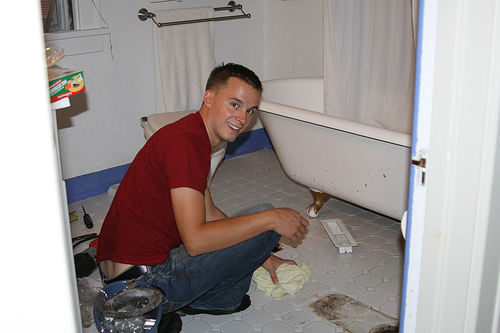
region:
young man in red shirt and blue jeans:
[90, 40, 305, 321]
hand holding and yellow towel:
[252, 249, 311, 303]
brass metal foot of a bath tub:
[301, 175, 336, 221]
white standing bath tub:
[242, 50, 416, 245]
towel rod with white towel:
[131, 2, 266, 120]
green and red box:
[43, 45, 92, 117]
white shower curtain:
[315, 0, 431, 145]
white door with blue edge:
[387, 0, 498, 332]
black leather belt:
[94, 252, 155, 289]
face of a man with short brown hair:
[197, 55, 271, 149]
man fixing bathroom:
[107, 52, 294, 322]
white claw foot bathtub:
[242, 58, 414, 233]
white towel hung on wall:
[142, 0, 257, 110]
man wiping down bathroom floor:
[243, 202, 341, 307]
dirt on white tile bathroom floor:
[307, 280, 370, 325]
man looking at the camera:
[105, 57, 278, 307]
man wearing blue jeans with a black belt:
[105, 196, 330, 324]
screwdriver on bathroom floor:
[76, 191, 101, 246]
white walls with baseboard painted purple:
[76, 125, 132, 202]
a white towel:
[130, 5, 252, 122]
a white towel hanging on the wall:
[130, 10, 257, 139]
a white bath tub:
[257, 53, 438, 240]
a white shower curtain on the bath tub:
[256, 0, 456, 217]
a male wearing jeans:
[116, 50, 284, 313]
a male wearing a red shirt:
[132, 57, 326, 289]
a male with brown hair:
[138, 40, 352, 279]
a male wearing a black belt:
[65, 58, 337, 308]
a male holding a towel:
[156, 61, 369, 328]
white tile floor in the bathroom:
[139, 147, 420, 323]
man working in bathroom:
[93, 50, 382, 330]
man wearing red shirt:
[80, 92, 233, 278]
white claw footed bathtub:
[250, 66, 401, 244]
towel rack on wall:
[138, 6, 273, 41]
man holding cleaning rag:
[247, 233, 323, 308]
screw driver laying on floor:
[71, 197, 106, 233]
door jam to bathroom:
[387, 128, 442, 185]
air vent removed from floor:
[319, 208, 360, 273]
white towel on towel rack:
[134, 6, 258, 135]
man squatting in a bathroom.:
[97, 13, 418, 310]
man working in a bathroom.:
[85, 10, 440, 320]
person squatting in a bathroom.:
[105, 0, 460, 305]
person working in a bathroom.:
[91, 35, 381, 315]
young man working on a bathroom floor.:
[97, 25, 437, 315]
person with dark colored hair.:
[195, 57, 280, 157]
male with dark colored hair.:
[195, 51, 280, 176]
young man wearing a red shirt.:
[115, 45, 280, 267]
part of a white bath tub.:
[265, 37, 387, 218]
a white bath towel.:
[145, 12, 210, 83]